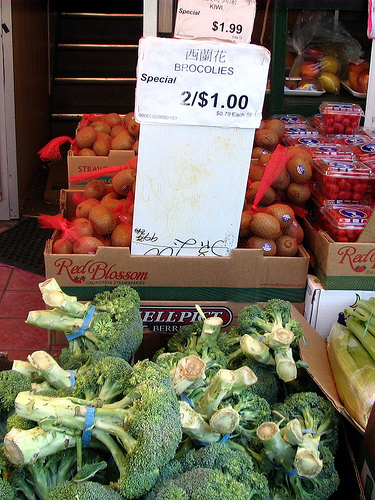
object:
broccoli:
[28, 275, 134, 310]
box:
[326, 420, 360, 498]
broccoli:
[15, 383, 168, 423]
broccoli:
[238, 327, 261, 365]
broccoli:
[175, 473, 267, 499]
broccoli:
[168, 314, 232, 361]